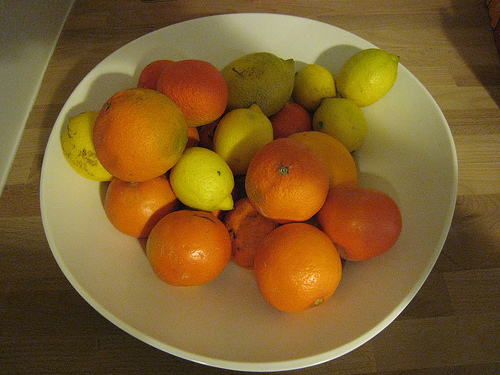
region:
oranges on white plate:
[106, 78, 342, 300]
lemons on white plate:
[165, 131, 211, 201]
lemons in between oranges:
[124, 103, 295, 207]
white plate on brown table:
[65, 35, 467, 315]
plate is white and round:
[65, 35, 445, 365]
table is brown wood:
[391, 11, 491, 101]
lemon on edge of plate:
[290, 27, 435, 107]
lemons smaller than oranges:
[285, 56, 385, 166]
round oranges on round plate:
[240, 127, 420, 334]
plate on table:
[15, 5, 420, 336]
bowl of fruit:
[22, 10, 474, 372]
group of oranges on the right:
[230, 131, 400, 311]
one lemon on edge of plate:
[337, 43, 403, 103]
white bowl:
[37, 10, 463, 372]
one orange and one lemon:
[97, 91, 236, 213]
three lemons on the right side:
[297, 49, 408, 146]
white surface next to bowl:
[2, 1, 54, 229]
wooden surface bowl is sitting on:
[20, 1, 494, 372]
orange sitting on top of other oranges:
[241, 137, 333, 223]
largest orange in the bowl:
[89, 87, 188, 176]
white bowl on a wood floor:
[33, 16, 495, 367]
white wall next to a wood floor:
[1, 1, 73, 221]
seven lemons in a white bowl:
[56, 48, 393, 215]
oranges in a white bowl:
[121, 70, 393, 305]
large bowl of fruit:
[41, 12, 462, 367]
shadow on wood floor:
[441, 2, 496, 122]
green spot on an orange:
[152, 96, 187, 162]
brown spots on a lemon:
[63, 122, 100, 181]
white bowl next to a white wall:
[0, 0, 458, 371]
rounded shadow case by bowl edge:
[31, 5, 294, 197]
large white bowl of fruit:
[37, 11, 454, 371]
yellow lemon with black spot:
[167, 145, 236, 220]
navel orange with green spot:
[92, 84, 189, 186]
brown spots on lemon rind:
[59, 110, 114, 189]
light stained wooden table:
[393, 7, 495, 353]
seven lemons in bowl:
[48, 30, 415, 216]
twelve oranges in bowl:
[92, 47, 409, 323]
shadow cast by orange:
[346, 152, 406, 214]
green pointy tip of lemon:
[387, 49, 402, 70]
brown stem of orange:
[275, 162, 297, 181]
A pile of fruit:
[73, 39, 404, 296]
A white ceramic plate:
[37, 10, 458, 373]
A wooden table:
[6, 4, 498, 373]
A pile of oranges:
[110, 57, 370, 304]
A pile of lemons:
[177, 30, 408, 212]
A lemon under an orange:
[56, 107, 110, 194]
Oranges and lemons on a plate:
[58, 42, 403, 311]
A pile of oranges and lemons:
[57, 50, 402, 310]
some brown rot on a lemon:
[59, 127, 99, 183]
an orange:
[320, 176, 402, 265]